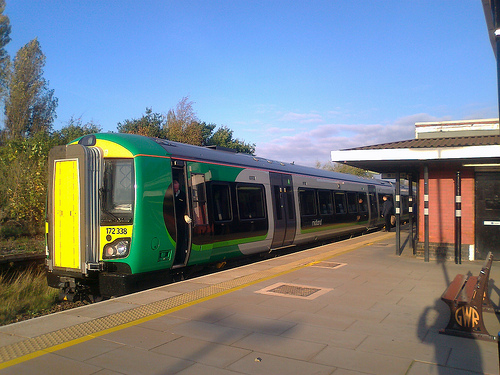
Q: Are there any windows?
A: Yes, there are windows.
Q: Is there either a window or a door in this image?
A: Yes, there are windows.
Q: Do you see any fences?
A: No, there are no fences.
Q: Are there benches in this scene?
A: Yes, there is a bench.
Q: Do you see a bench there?
A: Yes, there is a bench.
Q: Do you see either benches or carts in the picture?
A: Yes, there is a bench.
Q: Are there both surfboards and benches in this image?
A: No, there is a bench but no surfboards.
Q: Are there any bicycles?
A: No, there are no bicycles.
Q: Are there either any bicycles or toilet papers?
A: No, there are no bicycles or toilet papers.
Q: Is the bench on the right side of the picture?
A: Yes, the bench is on the right of the image.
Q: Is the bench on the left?
A: No, the bench is on the right of the image.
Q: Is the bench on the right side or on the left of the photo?
A: The bench is on the right of the image.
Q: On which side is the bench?
A: The bench is on the right of the image.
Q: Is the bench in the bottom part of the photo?
A: Yes, the bench is in the bottom of the image.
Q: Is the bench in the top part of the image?
A: No, the bench is in the bottom of the image.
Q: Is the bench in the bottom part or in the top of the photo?
A: The bench is in the bottom of the image.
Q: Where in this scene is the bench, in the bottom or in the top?
A: The bench is in the bottom of the image.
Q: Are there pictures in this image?
A: No, there are no pictures.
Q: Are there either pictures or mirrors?
A: No, there are no pictures or mirrors.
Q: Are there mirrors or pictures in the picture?
A: No, there are no pictures or mirrors.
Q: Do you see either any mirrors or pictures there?
A: No, there are no pictures or mirrors.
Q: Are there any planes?
A: No, there are no planes.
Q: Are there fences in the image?
A: No, there are no fences.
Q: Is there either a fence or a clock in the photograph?
A: No, there are no fences or clocks.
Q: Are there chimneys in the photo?
A: No, there are no chimneys.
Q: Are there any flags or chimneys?
A: No, there are no chimneys or flags.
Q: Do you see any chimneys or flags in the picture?
A: No, there are no chimneys or flags.